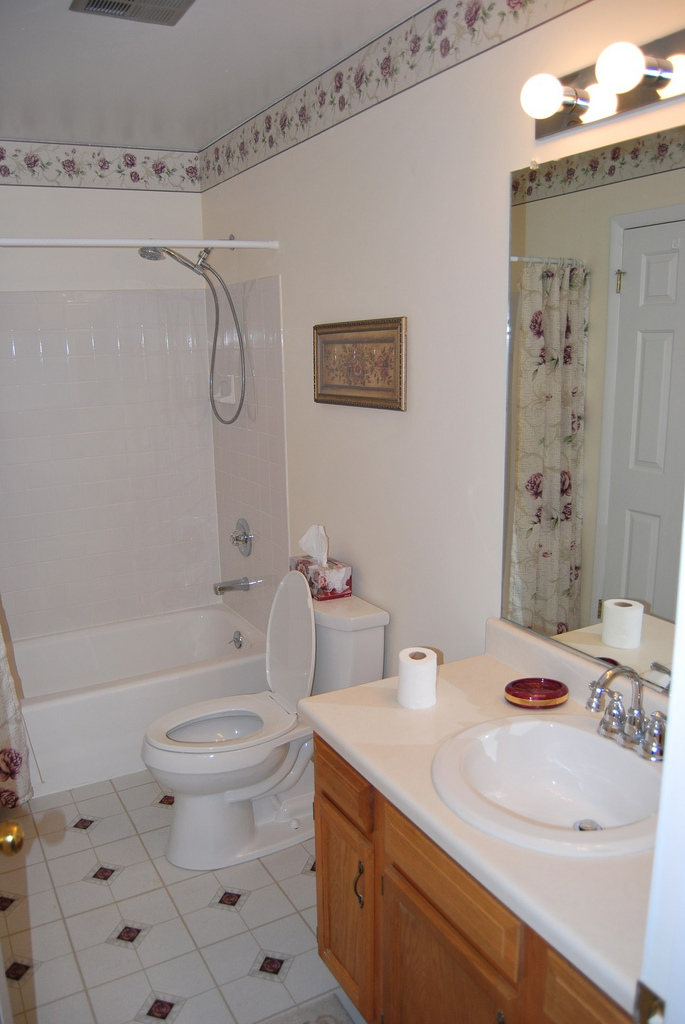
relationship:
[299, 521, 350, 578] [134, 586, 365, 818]
tissue on toilet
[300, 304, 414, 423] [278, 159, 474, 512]
frame on wall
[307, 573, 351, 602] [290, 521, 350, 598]
floral design on tissue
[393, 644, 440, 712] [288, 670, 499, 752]
paper roll on counter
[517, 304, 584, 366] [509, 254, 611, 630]
floral design on curtain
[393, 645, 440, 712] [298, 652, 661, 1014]
paper roll on counter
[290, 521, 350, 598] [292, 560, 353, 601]
tissue with flowers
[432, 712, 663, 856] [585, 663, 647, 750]
sink with faucet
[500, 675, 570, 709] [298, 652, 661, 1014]
dish on counter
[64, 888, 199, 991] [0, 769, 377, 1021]
tile on floor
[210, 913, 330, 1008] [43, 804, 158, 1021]
tile on the floor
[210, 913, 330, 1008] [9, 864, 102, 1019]
tile on the floor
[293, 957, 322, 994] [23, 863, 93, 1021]
tile on the floor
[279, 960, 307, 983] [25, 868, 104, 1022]
tile on the floor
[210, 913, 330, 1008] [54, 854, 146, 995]
tile on the floor